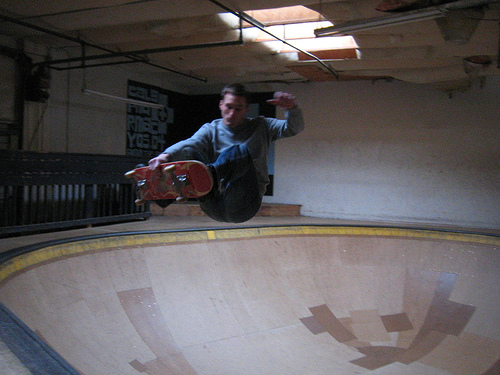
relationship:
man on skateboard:
[135, 84, 307, 224] [107, 144, 214, 207]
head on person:
[217, 79, 251, 129] [146, 80, 307, 222]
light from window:
[233, 19, 358, 73] [223, 2, 427, 76]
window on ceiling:
[223, 2, 427, 76] [6, 2, 498, 91]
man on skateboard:
[115, 80, 320, 229] [119, 156, 225, 206]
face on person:
[219, 90, 251, 128] [205, 72, 264, 124]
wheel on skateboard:
[163, 163, 178, 173] [108, 161, 225, 193]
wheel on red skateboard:
[173, 190, 185, 205] [123, 160, 214, 206]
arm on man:
[261, 90, 305, 139] [135, 84, 307, 224]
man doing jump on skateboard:
[135, 84, 307, 224] [123, 159, 212, 204]